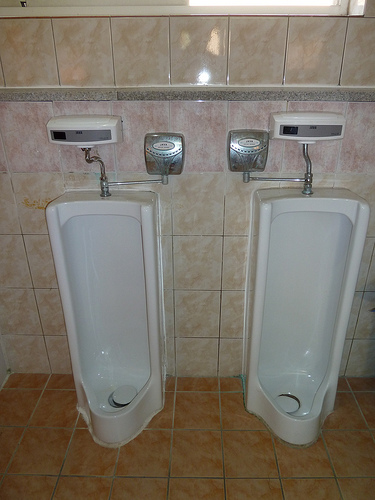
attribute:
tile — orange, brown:
[174, 389, 222, 432]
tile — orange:
[170, 426, 221, 479]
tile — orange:
[168, 478, 227, 497]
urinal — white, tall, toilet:
[243, 183, 372, 447]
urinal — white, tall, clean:
[45, 187, 168, 448]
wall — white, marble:
[1, 16, 372, 378]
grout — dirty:
[1, 470, 374, 482]